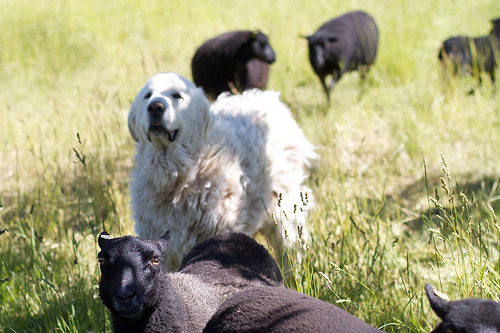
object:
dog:
[126, 72, 320, 270]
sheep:
[189, 28, 276, 97]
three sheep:
[188, 9, 500, 99]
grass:
[1, 0, 500, 332]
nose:
[146, 99, 168, 111]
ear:
[423, 284, 448, 318]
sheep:
[96, 233, 499, 332]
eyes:
[96, 253, 120, 264]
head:
[244, 27, 279, 66]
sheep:
[299, 11, 381, 101]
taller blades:
[2, 132, 494, 332]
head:
[128, 70, 210, 150]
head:
[96, 231, 169, 321]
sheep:
[97, 236, 283, 332]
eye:
[170, 91, 185, 105]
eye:
[144, 89, 155, 101]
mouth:
[145, 119, 181, 146]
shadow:
[129, 81, 272, 237]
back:
[197, 87, 301, 127]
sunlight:
[212, 87, 314, 248]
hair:
[131, 73, 318, 266]